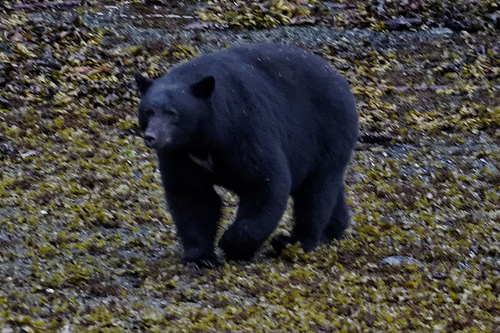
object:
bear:
[132, 40, 360, 267]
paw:
[181, 255, 225, 269]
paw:
[217, 238, 253, 263]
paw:
[274, 241, 316, 256]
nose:
[143, 133, 155, 143]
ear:
[190, 76, 216, 101]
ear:
[131, 71, 153, 93]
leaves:
[54, 141, 71, 152]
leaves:
[410, 313, 432, 333]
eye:
[163, 109, 175, 114]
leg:
[218, 167, 292, 262]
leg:
[157, 172, 223, 267]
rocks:
[151, 303, 157, 307]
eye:
[145, 109, 155, 116]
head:
[135, 73, 213, 151]